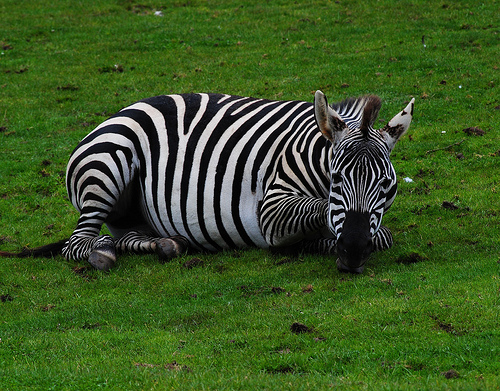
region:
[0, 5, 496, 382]
field of green grass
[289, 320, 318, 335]
ripped piece of grass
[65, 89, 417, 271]
zebra laying on ground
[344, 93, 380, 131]
mane on zebra's head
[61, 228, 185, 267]
bent legs on ground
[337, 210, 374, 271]
black nose on face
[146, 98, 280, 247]
stripes on zebra torso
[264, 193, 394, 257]
legs tucked under neck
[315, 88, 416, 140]
two ears on zebra head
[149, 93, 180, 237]
black stripe on white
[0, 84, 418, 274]
Black and white zebra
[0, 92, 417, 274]
Black and white zebra lying on grass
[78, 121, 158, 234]
Black stripe on zebra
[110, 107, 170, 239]
Black stripe on zebra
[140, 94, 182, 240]
Black stripe on zebra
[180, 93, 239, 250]
Black stripe on zebra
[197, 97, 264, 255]
Black stripe on zebra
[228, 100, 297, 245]
Black stripe on zebra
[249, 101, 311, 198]
Black stripe on zebra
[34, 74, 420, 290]
a zebra in the grass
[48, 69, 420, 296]
a zebra laying in the grass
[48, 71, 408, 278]
a zebra resting in the grass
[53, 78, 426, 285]
a tired zebra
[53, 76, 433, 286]
a zebra that is laying down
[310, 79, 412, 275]
the face of a zebra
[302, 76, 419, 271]
the head of a zebra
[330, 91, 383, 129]
the mane of a zebra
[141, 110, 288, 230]
stripes on a zebra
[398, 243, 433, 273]
a divet in the grass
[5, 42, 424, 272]
Zebra laying on the grass.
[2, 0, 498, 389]
Grass covering the ground.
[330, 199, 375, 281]
black nose on the zebra.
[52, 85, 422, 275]
black and white spots on the zebra.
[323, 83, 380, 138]
black and white mane on the zebra.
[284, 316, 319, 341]
dirt clod on the ground.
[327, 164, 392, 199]
Black eyes on the zebra.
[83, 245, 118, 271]
Black hoof on the zebra.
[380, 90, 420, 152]
black spots on the ear.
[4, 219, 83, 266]
black hair on the tail.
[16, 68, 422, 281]
a black and white zebra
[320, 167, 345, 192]
right eye of a zebra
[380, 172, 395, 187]
a left eye of a zebra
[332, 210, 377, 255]
a black nose on a zebra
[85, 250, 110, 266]
a gray hoof on a zebra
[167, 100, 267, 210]
black and white zebra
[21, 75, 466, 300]
a zebra on the grass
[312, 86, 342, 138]
a right ear on a zebra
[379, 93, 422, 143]
a left ear on a zebra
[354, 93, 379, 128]
black and white mane